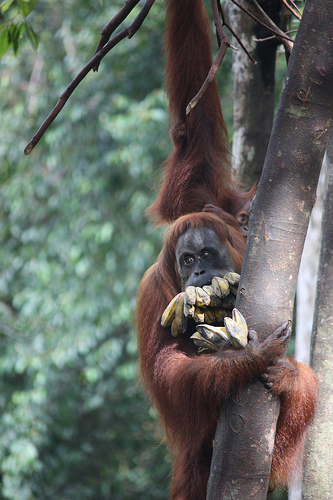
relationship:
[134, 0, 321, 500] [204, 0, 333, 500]
orangutan hanging from tree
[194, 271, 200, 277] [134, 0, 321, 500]
nostril on orangutan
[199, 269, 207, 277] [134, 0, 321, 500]
nostril on orangutan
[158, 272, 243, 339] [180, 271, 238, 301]
bananas in mouth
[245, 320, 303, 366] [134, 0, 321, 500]
hand of orangutan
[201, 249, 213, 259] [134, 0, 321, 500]
eye of orangutan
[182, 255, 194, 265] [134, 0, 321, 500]
eye of orangutan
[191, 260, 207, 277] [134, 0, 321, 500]
nose of orangutan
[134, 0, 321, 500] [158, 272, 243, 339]
orangutan holding bananas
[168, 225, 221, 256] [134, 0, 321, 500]
forehead of orangutan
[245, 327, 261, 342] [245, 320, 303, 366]
thumb on hand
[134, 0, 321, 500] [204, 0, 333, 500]
orangutan holding tree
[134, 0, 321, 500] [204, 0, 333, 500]
orangutan in tree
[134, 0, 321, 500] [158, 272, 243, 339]
orangutan has bananas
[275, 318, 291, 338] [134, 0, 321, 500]
finger of orangutan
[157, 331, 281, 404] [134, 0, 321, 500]
arm of orangutan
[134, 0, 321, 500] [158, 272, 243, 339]
orangutan with bananas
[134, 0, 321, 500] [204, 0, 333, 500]
orangutan climbing tree